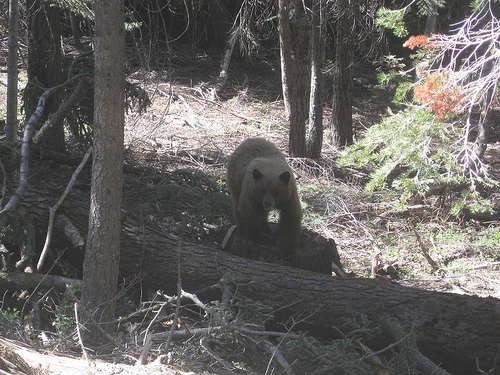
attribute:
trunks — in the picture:
[74, 3, 124, 349]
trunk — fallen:
[3, 171, 499, 373]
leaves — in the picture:
[343, 100, 477, 201]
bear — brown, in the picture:
[223, 132, 303, 259]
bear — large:
[199, 122, 368, 285]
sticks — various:
[122, 278, 383, 370]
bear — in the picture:
[213, 137, 304, 242]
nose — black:
[263, 203, 270, 211]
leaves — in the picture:
[413, 71, 466, 120]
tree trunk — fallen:
[141, 232, 493, 367]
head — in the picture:
[247, 167, 292, 212]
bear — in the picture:
[224, 135, 307, 250]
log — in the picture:
[124, 220, 499, 371]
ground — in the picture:
[135, 246, 427, 365]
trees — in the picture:
[0, 0, 499, 349]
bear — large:
[189, 105, 309, 257]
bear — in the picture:
[204, 131, 304, 229]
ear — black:
[245, 162, 266, 184]